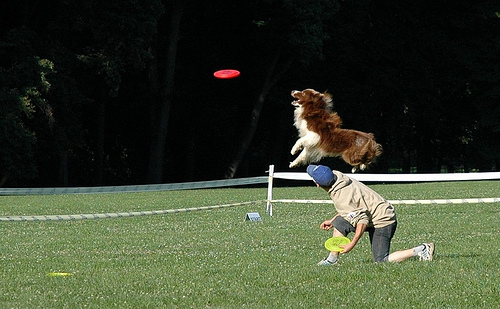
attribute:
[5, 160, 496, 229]
fence — long, white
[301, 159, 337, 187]
baseball cap — blue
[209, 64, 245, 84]
frisbee — red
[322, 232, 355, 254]
frisbee — yellow, round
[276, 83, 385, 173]
dog — brown, white, furry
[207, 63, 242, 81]
frisbee — red, colored, red-colored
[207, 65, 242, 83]
frisbee — yellow, colored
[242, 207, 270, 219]
placard — white, folded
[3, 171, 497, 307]
grassy area — large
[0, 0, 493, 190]
background — dark, dark-colored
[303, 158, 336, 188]
hat — blue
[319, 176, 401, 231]
jacket — tan, tan colored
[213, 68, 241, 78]
frisbee — red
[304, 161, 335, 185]
hat — Blue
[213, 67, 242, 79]
frisbee — round, red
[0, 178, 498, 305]
grass — green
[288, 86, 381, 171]
dog — brown, white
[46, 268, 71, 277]
frisbee — yellow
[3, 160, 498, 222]
fence — white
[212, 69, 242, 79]
frisbee — red